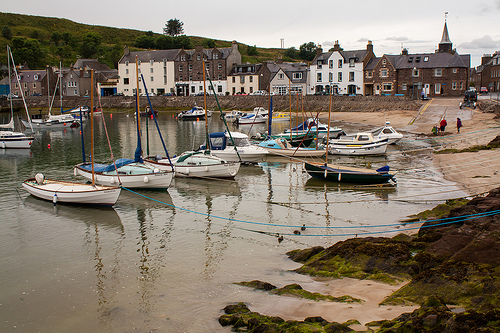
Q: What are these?
A: Boats.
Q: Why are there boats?
A: Travelling.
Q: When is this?
A: Daytime.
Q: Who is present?
A: Person.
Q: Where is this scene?
A: Harbor.